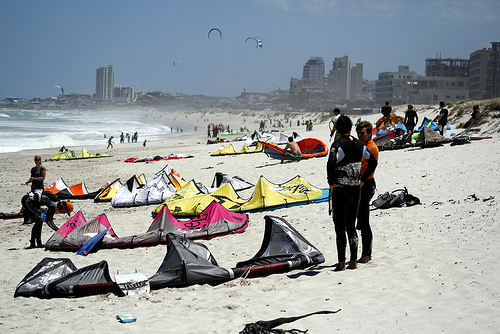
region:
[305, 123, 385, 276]
people standing on beach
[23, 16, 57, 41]
white clouds in blue sky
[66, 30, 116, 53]
white clouds in blue sky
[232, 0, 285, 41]
white clouds in blue sky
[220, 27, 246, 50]
white clouds in blue sky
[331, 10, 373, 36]
white clouds in blue sky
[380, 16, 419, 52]
white clouds in blue sky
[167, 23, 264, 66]
kites in the sky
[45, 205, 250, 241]
a pink and grey kite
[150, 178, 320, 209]
a yellow and white kite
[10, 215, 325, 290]
a grey and red kite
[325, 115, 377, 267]
people standing on the beach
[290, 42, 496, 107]
tall buildings off the beach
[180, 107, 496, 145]
people sitting on the beach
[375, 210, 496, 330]
sand of the beach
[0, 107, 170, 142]
the ocean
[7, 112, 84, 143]
waves of the water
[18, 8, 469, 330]
The people are on a beach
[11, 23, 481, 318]
The people are enjoying the beach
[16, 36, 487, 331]
The people are close to the ocean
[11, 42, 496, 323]
The people are enjoying some recreation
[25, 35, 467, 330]
The people are enjoying their day off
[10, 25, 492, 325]
The people are planning to swim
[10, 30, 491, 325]
The people are standing in the sand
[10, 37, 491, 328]
The people are in a coastal area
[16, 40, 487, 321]
The beach is close to a city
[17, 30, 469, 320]
The people are enjoying their day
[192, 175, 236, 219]
Yellow and black tarp laying down on the sand.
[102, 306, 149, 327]
Yellow and black tarp laying down on the sand.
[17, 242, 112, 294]
Yellow and black tarp laying down on the sand.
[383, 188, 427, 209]
Yellow and black tarp laying down on the sand.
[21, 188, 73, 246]
man in black kneeling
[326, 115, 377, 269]
person in black with hands on hips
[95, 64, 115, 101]
tall building by itself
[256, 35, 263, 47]
small white kite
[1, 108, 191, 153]
small section of beach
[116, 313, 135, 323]
square blue object in the sand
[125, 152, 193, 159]
red and white wind surf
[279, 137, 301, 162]
person in green shorts and no shirt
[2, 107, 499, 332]
light tan sandy beach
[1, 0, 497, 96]
blue overcast sky